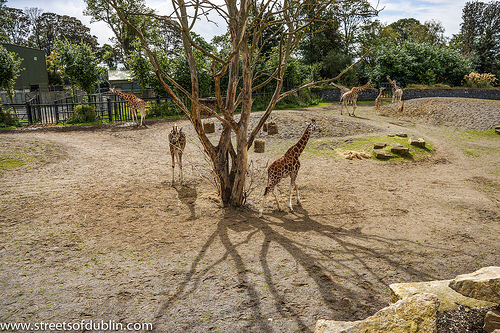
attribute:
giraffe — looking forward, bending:
[167, 122, 188, 187]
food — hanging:
[202, 123, 215, 132]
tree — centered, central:
[83, 1, 378, 206]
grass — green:
[281, 124, 447, 162]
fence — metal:
[5, 82, 499, 127]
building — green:
[96, 68, 222, 104]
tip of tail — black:
[264, 186, 270, 200]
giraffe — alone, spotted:
[109, 81, 147, 126]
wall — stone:
[321, 86, 500, 106]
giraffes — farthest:
[334, 73, 410, 115]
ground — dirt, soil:
[1, 97, 500, 331]